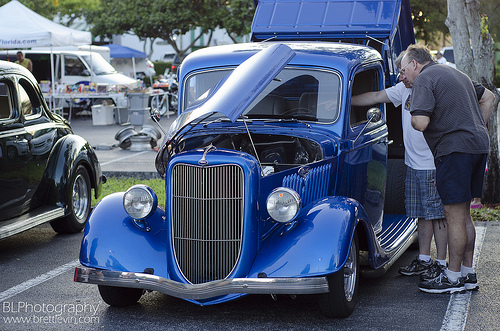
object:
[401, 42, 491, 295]
man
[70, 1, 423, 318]
truck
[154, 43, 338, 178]
hood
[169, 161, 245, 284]
grill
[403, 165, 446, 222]
shorts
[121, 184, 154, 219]
light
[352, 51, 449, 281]
guy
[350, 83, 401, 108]
arm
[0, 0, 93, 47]
canopy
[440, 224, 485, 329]
line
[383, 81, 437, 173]
top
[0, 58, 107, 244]
car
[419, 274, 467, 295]
shoe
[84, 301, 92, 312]
lettering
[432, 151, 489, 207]
bottoms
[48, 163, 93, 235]
tire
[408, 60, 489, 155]
shirt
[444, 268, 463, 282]
socks